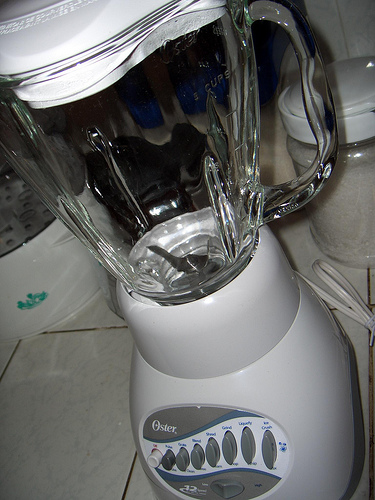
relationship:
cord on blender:
[306, 251, 374, 327] [1, 2, 366, 498]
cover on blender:
[1, 0, 224, 110] [1, 2, 366, 498]